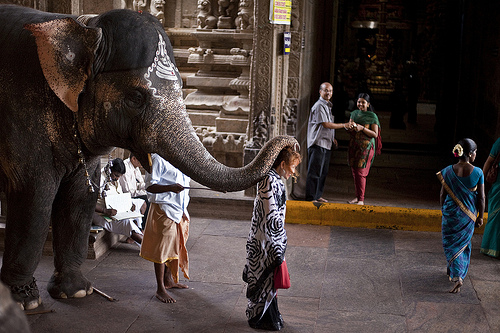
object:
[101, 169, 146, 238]
dress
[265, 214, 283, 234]
flower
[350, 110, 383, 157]
scarf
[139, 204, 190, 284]
skirt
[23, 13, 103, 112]
ear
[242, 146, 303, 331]
person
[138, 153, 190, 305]
person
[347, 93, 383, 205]
person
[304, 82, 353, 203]
person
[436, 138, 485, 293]
person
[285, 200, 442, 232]
line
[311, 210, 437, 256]
sidewalk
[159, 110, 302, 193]
trunk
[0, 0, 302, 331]
elephant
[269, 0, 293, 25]
sign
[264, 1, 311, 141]
wall